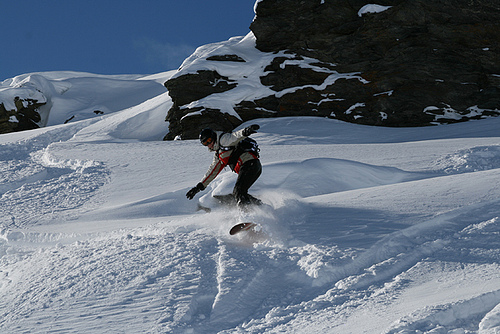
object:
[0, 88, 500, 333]
slope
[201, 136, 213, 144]
snow goggles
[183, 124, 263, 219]
man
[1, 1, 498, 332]
mountain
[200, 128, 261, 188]
jacket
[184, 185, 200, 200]
hand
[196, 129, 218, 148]
helmet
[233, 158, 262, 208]
pants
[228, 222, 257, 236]
snowboard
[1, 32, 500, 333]
snow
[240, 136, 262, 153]
backpack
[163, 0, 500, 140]
cliff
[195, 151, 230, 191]
arms